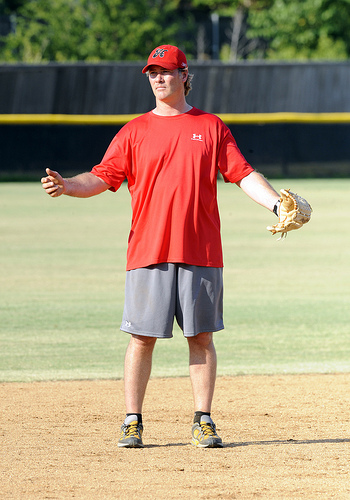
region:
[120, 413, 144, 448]
a grey and yellow shoe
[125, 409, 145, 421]
a black sock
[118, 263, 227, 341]
grey shorts on a man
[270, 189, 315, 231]
a brown mitt on a man's hand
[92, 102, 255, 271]
a red shirt on a man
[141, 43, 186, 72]
a red cap on a man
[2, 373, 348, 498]
brown dirt around a man's feet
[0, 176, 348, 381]
green grass behind a man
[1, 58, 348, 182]
a black wall behind a man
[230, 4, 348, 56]
a tree behind a wall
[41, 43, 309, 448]
The man is playing baseball.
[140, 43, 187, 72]
The man wears a red cap.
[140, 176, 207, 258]
The shirt is red.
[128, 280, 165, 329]
The shorts are grey.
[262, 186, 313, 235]
The man holds a glove.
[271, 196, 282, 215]
The man wears a watch.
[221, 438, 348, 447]
The man's shadow is on the ground.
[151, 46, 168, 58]
A logo is on the cap.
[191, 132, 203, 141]
A logo is on the shirt.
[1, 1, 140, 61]
Trees are behind the field.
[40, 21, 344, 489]
a man on a baseball field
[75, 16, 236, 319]
a man on a field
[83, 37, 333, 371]
a man with a baseball mit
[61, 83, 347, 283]
a man with a mitt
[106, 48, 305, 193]
a man wearing a hat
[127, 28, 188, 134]
a man weraing a red hat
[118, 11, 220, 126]
a man wearing a baseball hat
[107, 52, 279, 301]
a man wearing red shirt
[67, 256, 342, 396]
a green grass field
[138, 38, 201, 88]
a man wearing a red hat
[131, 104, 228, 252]
a man wearing a red shirt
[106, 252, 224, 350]
a man wearing grey shorts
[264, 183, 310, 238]
a man wearing a baseball glove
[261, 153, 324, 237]
a brown leather baseball glove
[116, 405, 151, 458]
a man wearing grey and yellow shoes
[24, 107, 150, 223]
a man holding his arm out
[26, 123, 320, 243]
a man holding both arms out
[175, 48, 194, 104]
a man with blonde hair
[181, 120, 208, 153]
a white emblem on a shirt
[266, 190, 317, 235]
a brown baseball glove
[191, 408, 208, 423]
a man's black sock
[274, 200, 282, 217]
part of a black watch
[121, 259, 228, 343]
a man's gray shorts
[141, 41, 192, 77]
a red baseball cap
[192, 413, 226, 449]
a man's gray and yellow shoe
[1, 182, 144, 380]
a section of green grass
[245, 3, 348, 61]
part of a green tree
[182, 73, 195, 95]
part of a man's short cut hair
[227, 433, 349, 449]
a long shadow